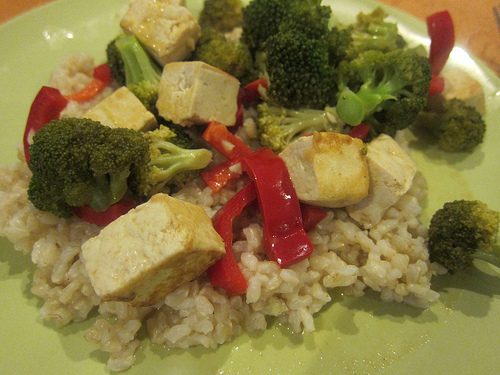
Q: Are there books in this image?
A: No, there are no books.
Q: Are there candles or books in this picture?
A: No, there are no books or candles.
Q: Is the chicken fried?
A: Yes, the chicken is fried.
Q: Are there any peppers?
A: Yes, there are peppers.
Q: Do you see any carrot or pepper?
A: Yes, there are peppers.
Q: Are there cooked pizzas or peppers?
A: Yes, there are cooked peppers.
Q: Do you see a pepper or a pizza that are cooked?
A: Yes, the peppers are cooked.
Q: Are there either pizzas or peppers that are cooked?
A: Yes, the peppers are cooked.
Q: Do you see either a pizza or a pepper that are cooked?
A: Yes, the peppers are cooked.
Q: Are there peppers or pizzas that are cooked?
A: Yes, the peppers are cooked.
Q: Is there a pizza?
A: No, there are no pizzas.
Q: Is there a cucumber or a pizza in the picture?
A: No, there are no pizzas or cucumbers.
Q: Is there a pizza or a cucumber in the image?
A: No, there are no pizzas or cucumbers.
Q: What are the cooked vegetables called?
A: The vegetables are peppers.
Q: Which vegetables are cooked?
A: The vegetables are peppers.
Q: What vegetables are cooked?
A: The vegetables are peppers.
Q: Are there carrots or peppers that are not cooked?
A: No, there are peppers but they are cooked.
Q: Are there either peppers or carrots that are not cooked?
A: No, there are peppers but they are cooked.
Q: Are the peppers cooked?
A: Yes, the peppers are cooked.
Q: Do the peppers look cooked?
A: Yes, the peppers are cooked.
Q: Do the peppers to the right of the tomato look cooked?
A: Yes, the peppers are cooked.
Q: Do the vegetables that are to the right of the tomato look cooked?
A: Yes, the peppers are cooked.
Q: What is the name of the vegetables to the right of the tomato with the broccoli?
A: The vegetables are peppers.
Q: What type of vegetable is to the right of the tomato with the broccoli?
A: The vegetables are peppers.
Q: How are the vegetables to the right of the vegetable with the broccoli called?
A: The vegetables are peppers.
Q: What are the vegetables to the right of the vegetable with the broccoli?
A: The vegetables are peppers.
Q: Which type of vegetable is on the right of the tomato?
A: The vegetables are peppers.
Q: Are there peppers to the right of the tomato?
A: Yes, there are peppers to the right of the tomato.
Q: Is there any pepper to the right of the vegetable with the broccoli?
A: Yes, there are peppers to the right of the tomato.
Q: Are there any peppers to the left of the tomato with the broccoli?
A: No, the peppers are to the right of the tomato.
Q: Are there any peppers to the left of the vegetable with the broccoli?
A: No, the peppers are to the right of the tomato.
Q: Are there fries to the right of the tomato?
A: No, there are peppers to the right of the tomato.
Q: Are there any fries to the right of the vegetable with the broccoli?
A: No, there are peppers to the right of the tomato.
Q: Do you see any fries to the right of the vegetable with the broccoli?
A: No, there are peppers to the right of the tomato.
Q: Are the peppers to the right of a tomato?
A: Yes, the peppers are to the right of a tomato.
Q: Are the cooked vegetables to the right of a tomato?
A: Yes, the peppers are to the right of a tomato.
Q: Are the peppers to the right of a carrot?
A: No, the peppers are to the right of a tomato.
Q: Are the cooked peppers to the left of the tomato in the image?
A: No, the peppers are to the right of the tomato.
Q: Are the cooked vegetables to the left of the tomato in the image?
A: No, the peppers are to the right of the tomato.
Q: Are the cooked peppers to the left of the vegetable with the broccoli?
A: No, the peppers are to the right of the tomato.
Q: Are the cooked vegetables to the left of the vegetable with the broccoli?
A: No, the peppers are to the right of the tomato.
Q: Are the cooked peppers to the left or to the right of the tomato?
A: The peppers are to the right of the tomato.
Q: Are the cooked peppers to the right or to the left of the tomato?
A: The peppers are to the right of the tomato.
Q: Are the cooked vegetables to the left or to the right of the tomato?
A: The peppers are to the right of the tomato.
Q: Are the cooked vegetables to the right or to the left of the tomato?
A: The peppers are to the right of the tomato.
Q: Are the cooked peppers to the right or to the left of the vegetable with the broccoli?
A: The peppers are to the right of the tomato.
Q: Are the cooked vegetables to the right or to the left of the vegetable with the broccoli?
A: The peppers are to the right of the tomato.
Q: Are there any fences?
A: No, there are no fences.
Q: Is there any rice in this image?
A: Yes, there is rice.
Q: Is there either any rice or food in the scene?
A: Yes, there is rice.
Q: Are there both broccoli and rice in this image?
A: Yes, there are both rice and broccoli.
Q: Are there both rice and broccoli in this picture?
A: Yes, there are both rice and broccoli.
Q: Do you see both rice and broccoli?
A: Yes, there are both rice and broccoli.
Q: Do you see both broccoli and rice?
A: Yes, there are both rice and broccoli.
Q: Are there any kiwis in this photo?
A: No, there are no kiwis.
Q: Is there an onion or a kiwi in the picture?
A: No, there are no kiwis or onions.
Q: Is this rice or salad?
A: This is rice.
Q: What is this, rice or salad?
A: This is rice.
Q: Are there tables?
A: Yes, there is a table.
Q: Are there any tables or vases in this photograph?
A: Yes, there is a table.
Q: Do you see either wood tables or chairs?
A: Yes, there is a wood table.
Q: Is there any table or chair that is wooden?
A: Yes, the table is wooden.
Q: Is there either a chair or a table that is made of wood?
A: Yes, the table is made of wood.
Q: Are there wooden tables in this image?
A: Yes, there is a wood table.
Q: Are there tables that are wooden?
A: Yes, there is a table that is wooden.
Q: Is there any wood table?
A: Yes, there is a table that is made of wood.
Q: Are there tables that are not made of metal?
A: Yes, there is a table that is made of wood.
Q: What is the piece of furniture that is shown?
A: The piece of furniture is a table.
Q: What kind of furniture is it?
A: The piece of furniture is a table.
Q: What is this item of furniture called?
A: This is a table.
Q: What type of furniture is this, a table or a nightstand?
A: This is a table.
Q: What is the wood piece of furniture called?
A: The piece of furniture is a table.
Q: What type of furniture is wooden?
A: The furniture is a table.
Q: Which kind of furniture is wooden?
A: The furniture is a table.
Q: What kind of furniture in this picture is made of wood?
A: The furniture is a table.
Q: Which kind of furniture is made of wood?
A: The furniture is a table.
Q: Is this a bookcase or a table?
A: This is a table.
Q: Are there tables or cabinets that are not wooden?
A: No, there is a table but it is wooden.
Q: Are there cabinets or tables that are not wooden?
A: No, there is a table but it is wooden.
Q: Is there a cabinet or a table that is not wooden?
A: No, there is a table but it is wooden.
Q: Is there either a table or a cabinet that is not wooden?
A: No, there is a table but it is wooden.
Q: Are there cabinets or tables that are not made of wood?
A: No, there is a table but it is made of wood.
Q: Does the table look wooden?
A: Yes, the table is wooden.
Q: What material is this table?
A: The table is made of wood.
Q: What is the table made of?
A: The table is made of wood.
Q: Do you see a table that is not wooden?
A: No, there is a table but it is wooden.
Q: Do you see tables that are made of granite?
A: No, there is a table but it is made of wood.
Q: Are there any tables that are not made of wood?
A: No, there is a table but it is made of wood.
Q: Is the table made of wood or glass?
A: The table is made of wood.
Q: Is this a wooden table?
A: Yes, this is a wooden table.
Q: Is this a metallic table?
A: No, this is a wooden table.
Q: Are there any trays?
A: No, there are no trays.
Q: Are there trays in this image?
A: No, there are no trays.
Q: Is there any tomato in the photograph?
A: Yes, there is a tomato.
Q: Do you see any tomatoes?
A: Yes, there is a tomato.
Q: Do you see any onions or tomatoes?
A: Yes, there is a tomato.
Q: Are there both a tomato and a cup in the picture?
A: No, there is a tomato but no cups.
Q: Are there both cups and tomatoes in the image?
A: No, there is a tomato but no cups.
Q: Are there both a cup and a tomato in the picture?
A: No, there is a tomato but no cups.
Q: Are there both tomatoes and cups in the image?
A: No, there is a tomato but no cups.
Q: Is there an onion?
A: No, there are no onions.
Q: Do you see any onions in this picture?
A: No, there are no onions.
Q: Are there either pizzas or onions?
A: No, there are no onions or pizzas.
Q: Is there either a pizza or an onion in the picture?
A: No, there are no onions or pizzas.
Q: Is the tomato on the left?
A: Yes, the tomato is on the left of the image.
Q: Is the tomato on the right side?
A: No, the tomato is on the left of the image.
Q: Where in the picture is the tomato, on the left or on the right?
A: The tomato is on the left of the image.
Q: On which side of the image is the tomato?
A: The tomato is on the left of the image.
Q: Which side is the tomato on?
A: The tomato is on the left of the image.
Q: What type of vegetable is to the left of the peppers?
A: The vegetable is a tomato.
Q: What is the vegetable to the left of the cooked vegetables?
A: The vegetable is a tomato.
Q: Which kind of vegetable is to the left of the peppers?
A: The vegetable is a tomato.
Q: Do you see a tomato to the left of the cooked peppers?
A: Yes, there is a tomato to the left of the peppers.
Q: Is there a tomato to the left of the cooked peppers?
A: Yes, there is a tomato to the left of the peppers.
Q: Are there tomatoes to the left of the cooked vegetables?
A: Yes, there is a tomato to the left of the peppers.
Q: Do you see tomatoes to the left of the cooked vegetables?
A: Yes, there is a tomato to the left of the peppers.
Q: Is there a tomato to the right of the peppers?
A: No, the tomato is to the left of the peppers.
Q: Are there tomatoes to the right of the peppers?
A: No, the tomato is to the left of the peppers.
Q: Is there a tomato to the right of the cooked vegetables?
A: No, the tomato is to the left of the peppers.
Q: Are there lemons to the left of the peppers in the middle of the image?
A: No, there is a tomato to the left of the peppers.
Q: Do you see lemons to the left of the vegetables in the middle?
A: No, there is a tomato to the left of the peppers.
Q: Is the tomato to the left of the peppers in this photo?
A: Yes, the tomato is to the left of the peppers.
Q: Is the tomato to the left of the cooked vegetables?
A: Yes, the tomato is to the left of the peppers.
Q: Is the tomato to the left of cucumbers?
A: No, the tomato is to the left of the peppers.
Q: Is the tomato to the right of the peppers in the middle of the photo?
A: No, the tomato is to the left of the peppers.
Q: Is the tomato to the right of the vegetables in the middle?
A: No, the tomato is to the left of the peppers.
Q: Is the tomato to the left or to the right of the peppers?
A: The tomato is to the left of the peppers.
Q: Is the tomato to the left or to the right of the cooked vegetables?
A: The tomato is to the left of the peppers.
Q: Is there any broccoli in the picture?
A: Yes, there is broccoli.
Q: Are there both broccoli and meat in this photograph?
A: No, there is broccoli but no meat.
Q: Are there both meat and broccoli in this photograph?
A: No, there is broccoli but no meat.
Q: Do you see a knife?
A: No, there are no knives.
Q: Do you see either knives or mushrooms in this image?
A: No, there are no knives or mushrooms.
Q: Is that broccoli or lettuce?
A: That is broccoli.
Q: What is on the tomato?
A: The broccoli is on the tomato.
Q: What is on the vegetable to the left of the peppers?
A: The broccoli is on the tomato.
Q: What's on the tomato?
A: The broccoli is on the tomato.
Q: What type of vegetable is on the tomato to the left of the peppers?
A: The vegetable is broccoli.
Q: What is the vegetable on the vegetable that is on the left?
A: The vegetable is broccoli.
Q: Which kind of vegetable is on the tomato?
A: The vegetable is broccoli.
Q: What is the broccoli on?
A: The broccoli is on the tomato.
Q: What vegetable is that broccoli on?
A: The broccoli is on the tomato.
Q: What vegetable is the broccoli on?
A: The broccoli is on the tomato.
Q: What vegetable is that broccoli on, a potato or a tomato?
A: The broccoli is on a tomato.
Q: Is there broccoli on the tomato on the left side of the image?
A: Yes, there is broccoli on the tomato.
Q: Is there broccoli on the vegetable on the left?
A: Yes, there is broccoli on the tomato.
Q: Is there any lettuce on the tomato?
A: No, there is broccoli on the tomato.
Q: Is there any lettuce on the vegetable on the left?
A: No, there is broccoli on the tomato.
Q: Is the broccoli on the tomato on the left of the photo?
A: Yes, the broccoli is on the tomato.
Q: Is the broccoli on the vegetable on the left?
A: Yes, the broccoli is on the tomato.